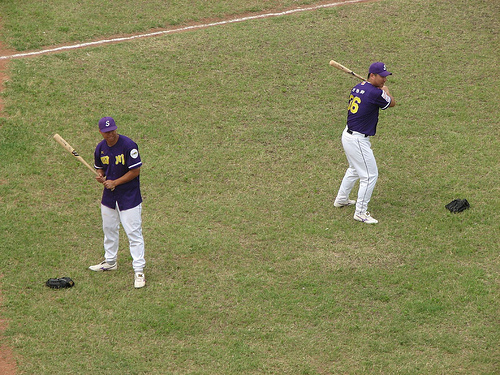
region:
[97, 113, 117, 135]
the cap is black in color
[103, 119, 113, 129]
a team logo is on the cap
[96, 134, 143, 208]
the man is wearing a shirt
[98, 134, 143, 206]
the shirt is black in color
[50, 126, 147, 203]
the man is holding a bat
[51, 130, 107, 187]
the bat is made of wood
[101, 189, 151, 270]
the man is wearing long pants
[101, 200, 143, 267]
the pants are white in color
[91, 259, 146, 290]
the man is wearing sneakers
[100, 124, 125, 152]
the eye of a man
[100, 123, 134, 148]
the mouth of a man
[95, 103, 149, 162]
the chin of a man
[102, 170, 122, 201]
the hand of a man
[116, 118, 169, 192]
the arm of a man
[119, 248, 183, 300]
the foot of a man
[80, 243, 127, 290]
the foot of a man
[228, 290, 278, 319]
patch of green grass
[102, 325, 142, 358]
patch of green grass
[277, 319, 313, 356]
patch of green grass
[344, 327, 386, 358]
patch of green grass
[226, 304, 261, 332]
patch of green grass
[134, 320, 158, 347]
patch of green grass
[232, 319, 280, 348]
patch of green grass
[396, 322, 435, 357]
patch of green grass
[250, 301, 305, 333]
patch of green grass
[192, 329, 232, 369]
patch of green grass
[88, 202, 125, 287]
leg of a person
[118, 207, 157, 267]
leg of a person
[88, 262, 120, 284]
feet of a person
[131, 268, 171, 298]
feet of a person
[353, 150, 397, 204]
leg of a person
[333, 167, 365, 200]
leg of a person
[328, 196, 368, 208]
feet of a person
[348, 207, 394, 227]
feet of a person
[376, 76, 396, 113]
arm of a person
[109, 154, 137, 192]
arm of a person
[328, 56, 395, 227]
a baseball playing ready to hit a ball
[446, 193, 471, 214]
a black catcher's mitt on the grass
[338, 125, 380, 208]
man wearing white pants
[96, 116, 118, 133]
man wearing a purple cap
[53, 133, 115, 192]
man holding a baseball bat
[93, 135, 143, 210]
man wearing a purple shirt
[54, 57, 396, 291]
two men standing on grass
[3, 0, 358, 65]
a white line on a baseball field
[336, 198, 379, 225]
man wearing white shoes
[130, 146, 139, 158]
a white circle on a purple shirt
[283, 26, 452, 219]
player on the field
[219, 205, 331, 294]
green grass on ground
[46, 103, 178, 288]
blue and white outfit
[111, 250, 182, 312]
foot of the person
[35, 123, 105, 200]
bat in man's hands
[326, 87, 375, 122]
number on back of jersey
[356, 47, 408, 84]
hat on head of person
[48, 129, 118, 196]
brown bat in batter's hand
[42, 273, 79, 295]
black catcher's mitt on grass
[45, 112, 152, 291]
baseball player standing with bat on green field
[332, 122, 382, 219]
pair of white baseball uniform pants on baseball player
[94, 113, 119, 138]
blue and white baseball hat on baseball player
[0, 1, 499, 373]
grass covered green baseball field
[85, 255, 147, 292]
white sneakers on baseball player